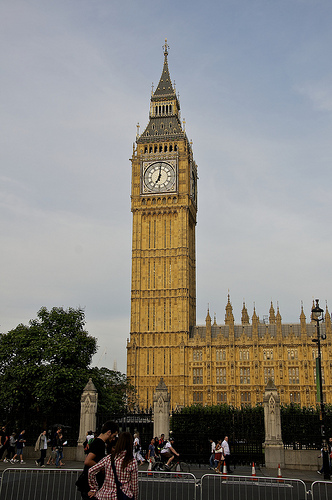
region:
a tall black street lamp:
[310, 297, 328, 483]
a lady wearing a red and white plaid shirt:
[86, 425, 138, 498]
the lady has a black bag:
[110, 454, 131, 499]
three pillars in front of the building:
[71, 375, 292, 468]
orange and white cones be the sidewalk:
[145, 461, 285, 483]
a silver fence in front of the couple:
[2, 469, 330, 499]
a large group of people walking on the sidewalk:
[3, 428, 241, 472]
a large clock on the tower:
[138, 152, 180, 198]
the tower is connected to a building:
[127, 33, 330, 405]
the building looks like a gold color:
[135, 258, 177, 367]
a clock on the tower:
[140, 159, 176, 195]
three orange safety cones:
[221, 462, 285, 481]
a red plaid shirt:
[86, 451, 137, 497]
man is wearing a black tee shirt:
[82, 437, 105, 484]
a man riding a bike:
[150, 437, 188, 474]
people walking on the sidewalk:
[3, 423, 68, 466]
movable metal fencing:
[1, 467, 330, 497]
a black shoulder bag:
[109, 456, 136, 498]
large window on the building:
[190, 366, 203, 384]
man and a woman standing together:
[80, 421, 139, 498]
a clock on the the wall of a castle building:
[136, 156, 180, 193]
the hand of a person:
[166, 442, 177, 448]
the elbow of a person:
[79, 456, 86, 463]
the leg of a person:
[166, 456, 178, 468]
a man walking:
[36, 429, 50, 473]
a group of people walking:
[2, 424, 71, 467]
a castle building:
[124, 55, 233, 405]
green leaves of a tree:
[15, 323, 90, 379]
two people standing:
[89, 426, 152, 498]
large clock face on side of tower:
[135, 150, 185, 200]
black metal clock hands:
[147, 160, 167, 186]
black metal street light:
[308, 298, 324, 354]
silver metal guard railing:
[197, 472, 305, 498]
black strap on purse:
[107, 453, 125, 494]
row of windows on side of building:
[186, 347, 262, 403]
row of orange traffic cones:
[221, 460, 284, 481]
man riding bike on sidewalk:
[148, 433, 193, 481]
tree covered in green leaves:
[0, 301, 95, 373]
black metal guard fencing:
[116, 406, 152, 433]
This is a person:
[222, 431, 239, 485]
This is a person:
[201, 430, 217, 472]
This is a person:
[319, 435, 331, 482]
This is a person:
[210, 437, 223, 488]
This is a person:
[161, 435, 182, 482]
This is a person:
[143, 435, 156, 487]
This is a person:
[131, 429, 147, 482]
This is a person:
[54, 422, 68, 471]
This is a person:
[31, 425, 49, 476]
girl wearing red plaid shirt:
[79, 427, 148, 497]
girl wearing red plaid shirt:
[80, 424, 150, 493]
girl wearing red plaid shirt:
[84, 428, 150, 494]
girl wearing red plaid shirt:
[75, 422, 148, 495]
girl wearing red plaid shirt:
[74, 425, 138, 498]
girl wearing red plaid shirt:
[80, 418, 144, 495]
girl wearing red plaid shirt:
[76, 418, 143, 498]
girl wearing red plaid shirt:
[78, 423, 142, 493]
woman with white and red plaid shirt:
[86, 432, 141, 499]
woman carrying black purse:
[85, 432, 140, 499]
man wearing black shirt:
[74, 421, 119, 499]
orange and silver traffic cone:
[221, 459, 230, 480]